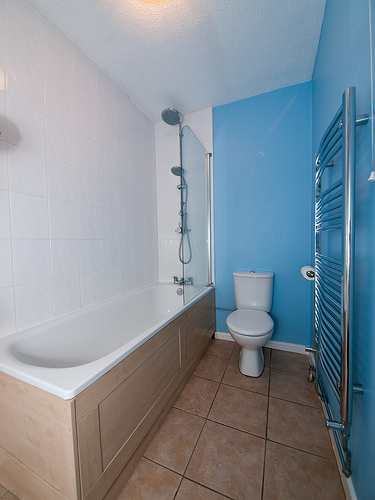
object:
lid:
[226, 308, 274, 336]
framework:
[303, 86, 353, 432]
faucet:
[173, 276, 193, 285]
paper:
[301, 265, 315, 281]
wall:
[212, 0, 375, 500]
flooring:
[104, 336, 349, 498]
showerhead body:
[179, 121, 184, 233]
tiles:
[117, 339, 348, 500]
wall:
[1, 0, 213, 335]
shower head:
[161, 108, 181, 125]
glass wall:
[182, 126, 211, 306]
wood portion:
[74, 285, 217, 500]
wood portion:
[0, 375, 79, 500]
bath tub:
[0, 283, 215, 499]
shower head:
[171, 166, 183, 177]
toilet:
[226, 307, 274, 379]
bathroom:
[0, 0, 375, 500]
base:
[239, 346, 267, 377]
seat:
[226, 307, 274, 350]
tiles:
[0, 3, 185, 337]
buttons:
[250, 271, 255, 273]